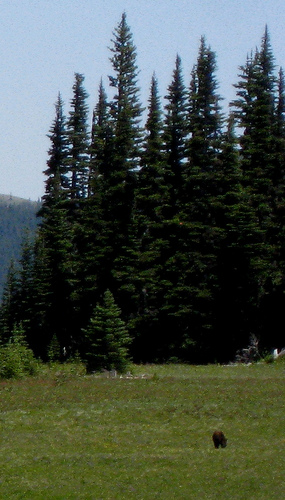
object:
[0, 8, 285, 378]
trees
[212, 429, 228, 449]
bear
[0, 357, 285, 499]
grass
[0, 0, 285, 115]
sky